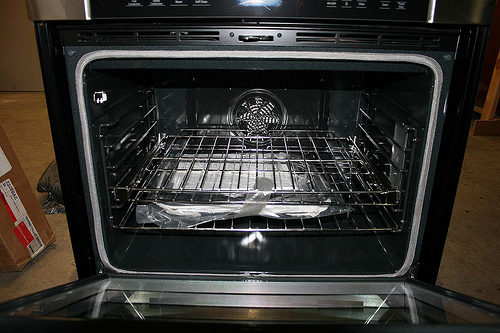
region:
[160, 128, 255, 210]
The oven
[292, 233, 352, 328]
The oven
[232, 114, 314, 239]
The oven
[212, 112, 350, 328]
The oven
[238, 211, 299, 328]
The oven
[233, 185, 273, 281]
The oven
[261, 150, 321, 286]
The oven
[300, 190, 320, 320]
The oven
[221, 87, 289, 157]
a fan in the back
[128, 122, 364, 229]
tin foil in the oven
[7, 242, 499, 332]
the door of the oven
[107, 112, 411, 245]
the racks in the oven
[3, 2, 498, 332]
a black oven set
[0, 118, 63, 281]
a cardboard box on the floor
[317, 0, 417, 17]
buttons on the oven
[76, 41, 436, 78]
seal around the door of the oven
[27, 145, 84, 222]
plastic bag on the ground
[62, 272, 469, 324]
oven window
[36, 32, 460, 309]
oven door is open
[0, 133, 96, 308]
the box is brown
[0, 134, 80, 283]
box beside the oven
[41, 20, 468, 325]
the oven is black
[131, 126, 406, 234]
the grills are silver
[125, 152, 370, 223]
plastic bag inside the oven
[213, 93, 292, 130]
a small fan in oven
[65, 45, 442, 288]
the line is gray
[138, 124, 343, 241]
the grills are made of steel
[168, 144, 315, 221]
papers inside the plastic bag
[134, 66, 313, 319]
An oven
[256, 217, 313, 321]
An oven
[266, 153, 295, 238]
An oven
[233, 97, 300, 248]
An oven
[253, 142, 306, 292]
An oven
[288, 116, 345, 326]
An oven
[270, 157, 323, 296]
An oven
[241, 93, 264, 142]
An oven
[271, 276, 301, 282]
edge of a oven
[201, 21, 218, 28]
top of an oven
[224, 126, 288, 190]
grill of an oven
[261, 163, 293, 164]
lower section of an oven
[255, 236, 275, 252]
lower floor of an oven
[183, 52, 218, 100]
upper floor of an oven